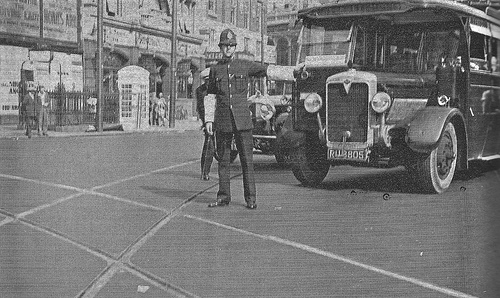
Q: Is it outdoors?
A: Yes, it is outdoors.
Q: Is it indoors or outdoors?
A: It is outdoors.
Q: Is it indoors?
A: No, it is outdoors.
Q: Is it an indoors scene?
A: No, it is outdoors.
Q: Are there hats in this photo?
A: Yes, there is a hat.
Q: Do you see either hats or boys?
A: Yes, there is a hat.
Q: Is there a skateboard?
A: No, there are no skateboards.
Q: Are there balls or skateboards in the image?
A: No, there are no skateboards or balls.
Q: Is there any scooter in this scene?
A: No, there are no scooters.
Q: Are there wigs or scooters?
A: No, there are no scooters or wigs.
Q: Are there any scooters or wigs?
A: No, there are no scooters or wigs.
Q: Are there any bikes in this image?
A: No, there are no bikes.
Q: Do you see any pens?
A: No, there are no pens.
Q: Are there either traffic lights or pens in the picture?
A: No, there are no pens or traffic lights.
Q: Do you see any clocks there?
A: No, there are no clocks.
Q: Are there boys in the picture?
A: No, there are no boys.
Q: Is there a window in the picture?
A: Yes, there are windows.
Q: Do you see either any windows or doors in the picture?
A: Yes, there are windows.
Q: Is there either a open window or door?
A: Yes, there are open windows.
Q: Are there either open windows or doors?
A: Yes, there are open windows.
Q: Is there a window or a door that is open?
A: Yes, the windows are open.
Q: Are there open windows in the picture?
A: Yes, there are open windows.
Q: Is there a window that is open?
A: Yes, there are windows that are open.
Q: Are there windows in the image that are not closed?
A: Yes, there are open windows.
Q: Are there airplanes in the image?
A: No, there are no airplanes.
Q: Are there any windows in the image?
A: Yes, there are windows.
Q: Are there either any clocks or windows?
A: Yes, there are windows.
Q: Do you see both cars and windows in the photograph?
A: Yes, there are both windows and a car.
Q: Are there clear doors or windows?
A: Yes, there are clear windows.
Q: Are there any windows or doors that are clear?
A: Yes, the windows are clear.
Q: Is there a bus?
A: Yes, there is a bus.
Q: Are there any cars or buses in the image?
A: Yes, there is a bus.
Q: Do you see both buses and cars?
A: Yes, there are both a bus and a car.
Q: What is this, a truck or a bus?
A: This is a bus.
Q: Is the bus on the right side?
A: Yes, the bus is on the right of the image.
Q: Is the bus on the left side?
A: No, the bus is on the right of the image.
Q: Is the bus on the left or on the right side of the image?
A: The bus is on the right of the image.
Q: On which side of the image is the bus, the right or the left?
A: The bus is on the right of the image.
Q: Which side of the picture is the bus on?
A: The bus is on the right of the image.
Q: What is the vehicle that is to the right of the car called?
A: The vehicle is a bus.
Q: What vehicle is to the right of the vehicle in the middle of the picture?
A: The vehicle is a bus.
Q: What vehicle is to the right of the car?
A: The vehicle is a bus.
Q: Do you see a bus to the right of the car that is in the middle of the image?
A: Yes, there is a bus to the right of the car.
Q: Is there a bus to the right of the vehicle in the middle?
A: Yes, there is a bus to the right of the car.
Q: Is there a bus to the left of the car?
A: No, the bus is to the right of the car.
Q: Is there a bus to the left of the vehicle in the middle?
A: No, the bus is to the right of the car.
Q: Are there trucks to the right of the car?
A: No, there is a bus to the right of the car.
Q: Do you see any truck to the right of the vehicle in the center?
A: No, there is a bus to the right of the car.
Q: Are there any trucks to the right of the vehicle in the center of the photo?
A: No, there is a bus to the right of the car.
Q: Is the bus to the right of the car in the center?
A: Yes, the bus is to the right of the car.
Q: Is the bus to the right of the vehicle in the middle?
A: Yes, the bus is to the right of the car.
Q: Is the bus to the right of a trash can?
A: No, the bus is to the right of the car.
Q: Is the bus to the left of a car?
A: No, the bus is to the right of a car.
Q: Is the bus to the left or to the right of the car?
A: The bus is to the right of the car.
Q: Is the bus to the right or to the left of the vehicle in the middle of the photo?
A: The bus is to the right of the car.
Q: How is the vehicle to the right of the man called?
A: The vehicle is a bus.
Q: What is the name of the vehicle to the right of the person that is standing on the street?
A: The vehicle is a bus.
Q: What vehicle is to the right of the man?
A: The vehicle is a bus.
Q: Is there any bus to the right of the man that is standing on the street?
A: Yes, there is a bus to the right of the man.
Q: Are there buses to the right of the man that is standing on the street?
A: Yes, there is a bus to the right of the man.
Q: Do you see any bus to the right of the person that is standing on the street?
A: Yes, there is a bus to the right of the man.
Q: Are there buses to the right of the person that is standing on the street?
A: Yes, there is a bus to the right of the man.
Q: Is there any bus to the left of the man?
A: No, the bus is to the right of the man.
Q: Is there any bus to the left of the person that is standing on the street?
A: No, the bus is to the right of the man.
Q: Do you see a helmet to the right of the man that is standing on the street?
A: No, there is a bus to the right of the man.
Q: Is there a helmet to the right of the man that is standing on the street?
A: No, there is a bus to the right of the man.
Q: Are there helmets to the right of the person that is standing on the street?
A: No, there is a bus to the right of the man.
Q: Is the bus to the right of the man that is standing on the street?
A: Yes, the bus is to the right of the man.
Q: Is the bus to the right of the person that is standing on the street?
A: Yes, the bus is to the right of the man.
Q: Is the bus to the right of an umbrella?
A: No, the bus is to the right of the man.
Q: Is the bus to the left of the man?
A: No, the bus is to the right of the man.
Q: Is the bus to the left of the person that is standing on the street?
A: No, the bus is to the right of the man.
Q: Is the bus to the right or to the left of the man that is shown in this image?
A: The bus is to the right of the man.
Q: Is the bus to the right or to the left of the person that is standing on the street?
A: The bus is to the right of the man.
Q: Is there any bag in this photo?
A: No, there are no bags.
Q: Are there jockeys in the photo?
A: No, there are no jockeys.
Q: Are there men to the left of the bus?
A: Yes, there is a man to the left of the bus.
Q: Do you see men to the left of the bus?
A: Yes, there is a man to the left of the bus.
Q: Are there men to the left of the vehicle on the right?
A: Yes, there is a man to the left of the bus.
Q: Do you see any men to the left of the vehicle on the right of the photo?
A: Yes, there is a man to the left of the bus.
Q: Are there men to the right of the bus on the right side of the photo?
A: No, the man is to the left of the bus.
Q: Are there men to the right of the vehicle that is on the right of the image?
A: No, the man is to the left of the bus.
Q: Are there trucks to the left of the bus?
A: No, there is a man to the left of the bus.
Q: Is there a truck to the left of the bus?
A: No, there is a man to the left of the bus.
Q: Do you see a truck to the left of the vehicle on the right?
A: No, there is a man to the left of the bus.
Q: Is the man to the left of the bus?
A: Yes, the man is to the left of the bus.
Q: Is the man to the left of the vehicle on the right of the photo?
A: Yes, the man is to the left of the bus.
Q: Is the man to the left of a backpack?
A: No, the man is to the left of the bus.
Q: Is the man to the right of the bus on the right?
A: No, the man is to the left of the bus.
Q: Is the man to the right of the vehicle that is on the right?
A: No, the man is to the left of the bus.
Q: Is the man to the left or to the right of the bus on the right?
A: The man is to the left of the bus.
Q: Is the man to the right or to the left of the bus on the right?
A: The man is to the left of the bus.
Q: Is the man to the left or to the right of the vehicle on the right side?
A: The man is to the left of the bus.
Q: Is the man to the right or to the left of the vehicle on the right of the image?
A: The man is to the left of the bus.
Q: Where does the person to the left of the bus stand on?
A: The man stands on the street.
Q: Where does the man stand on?
A: The man stands on the street.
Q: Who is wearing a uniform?
A: The man is wearing a uniform.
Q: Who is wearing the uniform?
A: The man is wearing a uniform.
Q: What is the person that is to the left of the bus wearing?
A: The man is wearing a uniform.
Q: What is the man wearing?
A: The man is wearing a uniform.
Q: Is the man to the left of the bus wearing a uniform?
A: Yes, the man is wearing a uniform.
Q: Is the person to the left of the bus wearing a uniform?
A: Yes, the man is wearing a uniform.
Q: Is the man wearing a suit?
A: No, the man is wearing a uniform.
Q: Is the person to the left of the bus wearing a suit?
A: No, the man is wearing a uniform.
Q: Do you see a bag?
A: No, there are no bags.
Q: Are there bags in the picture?
A: No, there are no bags.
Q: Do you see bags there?
A: No, there are no bags.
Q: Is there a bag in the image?
A: No, there are no bags.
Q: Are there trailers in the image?
A: No, there are no trailers.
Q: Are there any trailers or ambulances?
A: No, there are no trailers or ambulances.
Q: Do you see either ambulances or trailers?
A: No, there are no trailers or ambulances.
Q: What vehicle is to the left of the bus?
A: The vehicle is a car.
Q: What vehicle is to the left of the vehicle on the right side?
A: The vehicle is a car.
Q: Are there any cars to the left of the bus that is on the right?
A: Yes, there is a car to the left of the bus.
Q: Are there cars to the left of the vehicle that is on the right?
A: Yes, there is a car to the left of the bus.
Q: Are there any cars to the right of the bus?
A: No, the car is to the left of the bus.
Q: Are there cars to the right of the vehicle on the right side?
A: No, the car is to the left of the bus.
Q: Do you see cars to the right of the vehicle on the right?
A: No, the car is to the left of the bus.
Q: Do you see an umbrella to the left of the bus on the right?
A: No, there is a car to the left of the bus.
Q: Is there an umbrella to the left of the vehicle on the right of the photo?
A: No, there is a car to the left of the bus.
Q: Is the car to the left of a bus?
A: Yes, the car is to the left of a bus.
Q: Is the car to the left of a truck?
A: No, the car is to the left of a bus.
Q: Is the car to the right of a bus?
A: No, the car is to the left of a bus.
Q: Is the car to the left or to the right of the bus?
A: The car is to the left of the bus.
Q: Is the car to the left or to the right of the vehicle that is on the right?
A: The car is to the left of the bus.